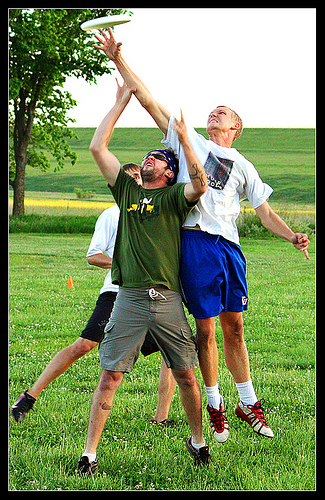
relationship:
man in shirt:
[10, 158, 185, 438] [84, 196, 130, 295]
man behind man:
[10, 158, 185, 438] [74, 78, 216, 480]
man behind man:
[10, 158, 185, 438] [98, 55, 312, 446]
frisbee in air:
[80, 15, 132, 31] [4, 9, 318, 130]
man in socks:
[98, 55, 312, 446] [204, 384, 223, 410]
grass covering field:
[7, 127, 314, 491] [11, 7, 323, 481]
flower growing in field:
[33, 204, 38, 205] [21, 194, 102, 216]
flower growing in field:
[53, 199, 55, 201] [21, 194, 102, 216]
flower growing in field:
[83, 202, 84, 203] [21, 194, 102, 216]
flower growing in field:
[98, 204, 99, 205] [21, 194, 102, 216]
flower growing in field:
[26, 199, 27, 200] [21, 194, 102, 216]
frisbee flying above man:
[77, 15, 129, 29] [98, 55, 312, 446]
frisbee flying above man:
[77, 15, 129, 29] [74, 78, 216, 480]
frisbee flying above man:
[77, 15, 129, 29] [10, 158, 185, 438]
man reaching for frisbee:
[74, 78, 216, 480] [81, 13, 132, 32]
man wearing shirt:
[74, 78, 216, 480] [105, 164, 200, 290]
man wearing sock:
[92, 27, 310, 444] [229, 378, 259, 408]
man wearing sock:
[92, 27, 310, 444] [201, 378, 227, 415]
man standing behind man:
[10, 158, 185, 438] [98, 55, 312, 446]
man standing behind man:
[10, 158, 185, 438] [74, 78, 216, 480]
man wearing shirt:
[10, 158, 185, 438] [83, 200, 119, 292]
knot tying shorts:
[146, 287, 164, 297] [91, 280, 198, 371]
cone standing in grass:
[54, 268, 81, 297] [14, 258, 55, 292]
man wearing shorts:
[98, 55, 312, 446] [177, 227, 248, 317]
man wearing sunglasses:
[74, 78, 216, 480] [141, 151, 170, 168]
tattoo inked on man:
[187, 160, 205, 192] [74, 78, 216, 480]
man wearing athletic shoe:
[92, 27, 310, 444] [206, 394, 230, 443]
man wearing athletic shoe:
[92, 27, 310, 444] [234, 398, 274, 438]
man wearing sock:
[92, 27, 310, 444] [205, 384, 222, 410]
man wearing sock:
[92, 27, 310, 444] [234, 377, 261, 406]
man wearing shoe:
[74, 78, 216, 480] [72, 455, 100, 478]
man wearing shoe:
[74, 78, 216, 480] [182, 436, 214, 466]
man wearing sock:
[74, 78, 216, 480] [189, 436, 203, 449]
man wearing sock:
[92, 27, 310, 444] [81, 450, 96, 461]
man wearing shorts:
[74, 78, 216, 480] [95, 285, 202, 370]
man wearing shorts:
[92, 27, 310, 444] [175, 222, 252, 317]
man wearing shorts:
[9, 163, 177, 428] [79, 292, 162, 351]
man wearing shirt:
[9, 163, 177, 428] [83, 201, 124, 296]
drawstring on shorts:
[144, 284, 161, 302] [115, 289, 194, 375]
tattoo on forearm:
[189, 163, 205, 186] [188, 176, 208, 195]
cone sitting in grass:
[67, 276, 75, 289] [7, 127, 314, 491]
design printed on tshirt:
[206, 149, 231, 188] [155, 117, 252, 275]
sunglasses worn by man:
[141, 153, 169, 168] [74, 78, 216, 480]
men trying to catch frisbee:
[25, 13, 307, 489] [77, 12, 131, 29]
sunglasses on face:
[136, 142, 177, 168] [136, 145, 171, 189]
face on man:
[136, 145, 171, 189] [128, 142, 197, 446]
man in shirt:
[128, 142, 197, 446] [116, 185, 178, 284]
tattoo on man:
[189, 163, 205, 186] [74, 78, 216, 480]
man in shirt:
[74, 78, 216, 480] [116, 185, 178, 284]